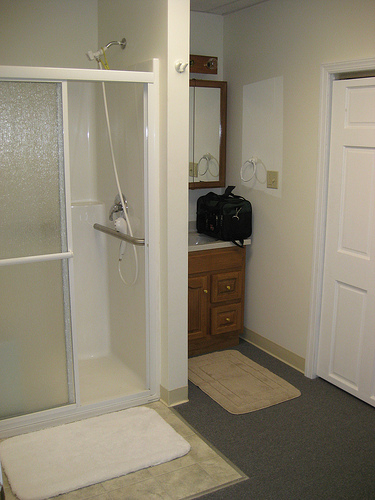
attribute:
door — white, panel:
[315, 73, 373, 409]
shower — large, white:
[0, 3, 169, 440]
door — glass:
[0, 80, 106, 389]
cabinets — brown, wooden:
[182, 245, 249, 357]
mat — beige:
[188, 344, 303, 414]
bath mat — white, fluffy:
[0, 403, 186, 498]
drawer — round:
[207, 268, 245, 303]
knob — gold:
[224, 283, 233, 291]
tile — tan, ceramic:
[154, 473, 216, 495]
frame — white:
[0, 55, 373, 441]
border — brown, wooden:
[220, 81, 227, 183]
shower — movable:
[73, 34, 149, 245]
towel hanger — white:
[174, 60, 192, 77]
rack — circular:
[239, 156, 258, 187]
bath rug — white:
[2, 406, 192, 489]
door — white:
[296, 54, 373, 399]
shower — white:
[79, 30, 129, 63]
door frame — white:
[301, 56, 373, 381]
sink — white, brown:
[187, 231, 251, 356]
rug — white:
[2, 406, 197, 498]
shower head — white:
[112, 214, 128, 261]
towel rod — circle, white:
[237, 157, 257, 184]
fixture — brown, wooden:
[189, 53, 218, 76]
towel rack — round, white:
[236, 155, 260, 185]